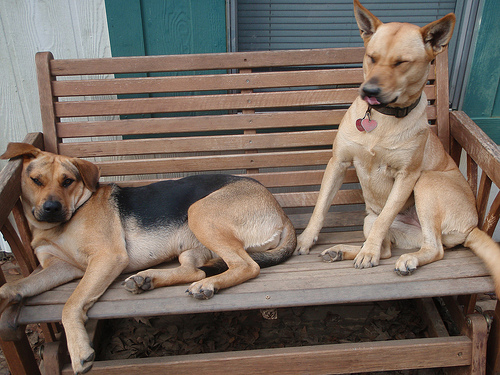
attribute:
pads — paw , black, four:
[121, 274, 155, 297]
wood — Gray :
[1, 0, 127, 185]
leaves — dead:
[128, 322, 343, 348]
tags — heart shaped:
[356, 113, 378, 133]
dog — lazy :
[290, 4, 487, 293]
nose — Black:
[357, 75, 384, 96]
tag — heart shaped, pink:
[356, 117, 378, 132]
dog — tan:
[3, 118, 300, 370]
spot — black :
[110, 165, 220, 240]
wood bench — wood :
[0, 44, 499, 374]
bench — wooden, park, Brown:
[3, 43, 498, 372]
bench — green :
[44, 47, 344, 201]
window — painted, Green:
[232, 0, 474, 108]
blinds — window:
[255, 15, 293, 35]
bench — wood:
[32, 53, 456, 258]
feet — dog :
[133, 279, 150, 289]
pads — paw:
[177, 259, 219, 303]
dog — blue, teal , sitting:
[295, 0, 498, 300]